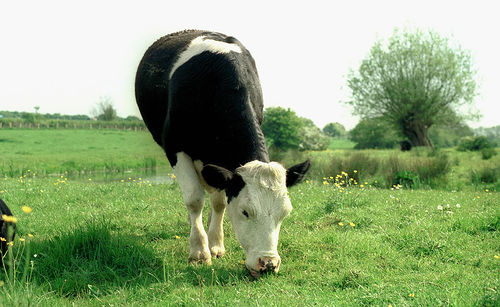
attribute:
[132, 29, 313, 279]
cow — eating., black., white.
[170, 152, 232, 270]
legs — white.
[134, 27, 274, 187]
body — black.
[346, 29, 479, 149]
tree — green., mature., leafy.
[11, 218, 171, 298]
patch — green., grassy.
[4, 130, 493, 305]
ground — lush., grassy., green.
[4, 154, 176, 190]
pond — small., behind.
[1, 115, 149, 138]
fence — long.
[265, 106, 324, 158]
bush — green., leafy.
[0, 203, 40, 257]
flowers — yellow.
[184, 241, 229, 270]
feet — white.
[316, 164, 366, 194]
flowers — yellow